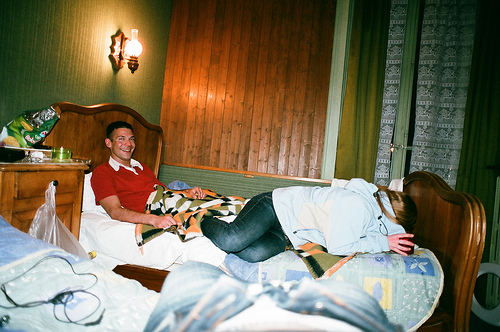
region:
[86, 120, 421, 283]
a couple lying in bed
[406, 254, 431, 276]
a blue butterfly pattern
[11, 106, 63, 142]
a crumple bag of potato chips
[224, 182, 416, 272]
a woman hiding her face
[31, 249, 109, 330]
a black cord on the bed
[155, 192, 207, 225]
a multicolored quilt on a lap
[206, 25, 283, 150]
brown wooden window blinds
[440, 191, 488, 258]
an oak foot board on a bed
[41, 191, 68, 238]
a plastic bag hanging on the nightstand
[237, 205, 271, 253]
blue jeans covering legs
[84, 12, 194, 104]
a single light on the wall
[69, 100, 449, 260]
two people on a bed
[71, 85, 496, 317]
a bed with two people on it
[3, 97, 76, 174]
a bag of chips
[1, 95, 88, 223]
a bag of chips on a night stand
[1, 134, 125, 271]
a wooden night stand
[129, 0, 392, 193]
a wooden wall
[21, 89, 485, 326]
a wooden bed frame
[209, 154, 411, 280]
a person wearing blue jeans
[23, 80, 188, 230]
a person wearing a red shirt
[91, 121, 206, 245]
Man lying in bed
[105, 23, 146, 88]
Light mounted to wall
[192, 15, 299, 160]
Natural wood paneling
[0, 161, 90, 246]
Nightstand next to bed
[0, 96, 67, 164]
Bag of chips on nightstand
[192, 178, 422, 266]
Girl lying on the bed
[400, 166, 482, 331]
Footboard of the bed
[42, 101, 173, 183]
Headboard of the bed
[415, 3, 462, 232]
Sheer drapes hung on the door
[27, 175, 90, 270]
Bag hanging from knob on drawer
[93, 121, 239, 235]
a man lying on bed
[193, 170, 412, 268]
a woman lying on bed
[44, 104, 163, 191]
a brown wood headboard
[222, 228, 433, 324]
a light blue quilt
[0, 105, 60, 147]
an open bag of chips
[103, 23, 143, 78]
a wall mounted light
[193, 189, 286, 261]
a pair of women's blue jeans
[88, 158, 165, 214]
a man's red shirt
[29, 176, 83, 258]
a hanging clear plastic bag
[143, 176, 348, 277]
a green white and orange quilt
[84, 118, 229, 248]
guy laying in bed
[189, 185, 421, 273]
person laying on bed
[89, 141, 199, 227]
red and white shirt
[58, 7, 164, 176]
lamp on wall over bed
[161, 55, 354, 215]
wood paneling on wall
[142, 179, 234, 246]
green, white, and orange cover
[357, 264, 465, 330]
blue, yellow, and white cover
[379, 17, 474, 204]
green and white drape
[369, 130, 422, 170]
door knob on door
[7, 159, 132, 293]
plastic bag hanging on knob